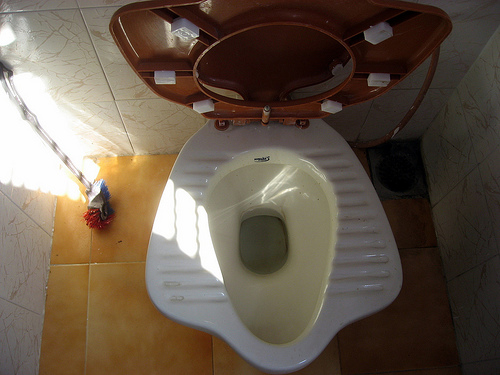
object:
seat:
[103, 6, 453, 132]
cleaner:
[371, 131, 430, 201]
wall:
[452, 30, 485, 68]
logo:
[253, 156, 271, 163]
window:
[1, 54, 71, 193]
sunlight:
[7, 96, 76, 194]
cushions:
[136, 31, 435, 140]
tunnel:
[236, 210, 291, 270]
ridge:
[187, 154, 232, 162]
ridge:
[303, 143, 345, 159]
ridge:
[155, 262, 210, 275]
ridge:
[338, 241, 390, 251]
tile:
[0, 198, 53, 331]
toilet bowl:
[106, 0, 451, 368]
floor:
[44, 154, 148, 373]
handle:
[4, 75, 88, 192]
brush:
[80, 177, 117, 231]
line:
[173, 180, 209, 189]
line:
[153, 252, 206, 260]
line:
[157, 291, 227, 303]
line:
[338, 240, 389, 250]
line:
[335, 199, 369, 207]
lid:
[109, 1, 454, 129]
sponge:
[169, 21, 202, 47]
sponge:
[366, 70, 392, 87]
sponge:
[192, 99, 215, 114]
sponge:
[363, 21, 393, 45]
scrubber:
[2, 72, 115, 231]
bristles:
[83, 180, 115, 230]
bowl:
[223, 188, 321, 298]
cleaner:
[1, 65, 115, 229]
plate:
[370, 136, 433, 215]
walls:
[25, 48, 132, 154]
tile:
[46, 265, 90, 375]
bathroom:
[45, 117, 496, 375]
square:
[153, 69, 177, 86]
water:
[234, 204, 293, 277]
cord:
[356, 42, 440, 148]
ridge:
[336, 251, 389, 265]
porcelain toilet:
[140, 117, 403, 373]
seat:
[141, 109, 404, 371]